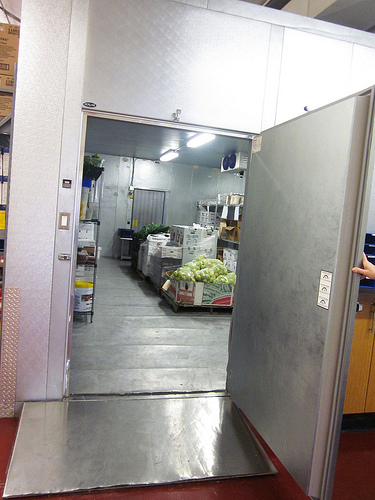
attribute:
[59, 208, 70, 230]
switch — plasic, white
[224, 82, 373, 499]
door — silver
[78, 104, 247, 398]
cooler — silver, refrigerated, big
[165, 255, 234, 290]
apples — green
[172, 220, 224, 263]
boxes — white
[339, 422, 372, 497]
floor — red